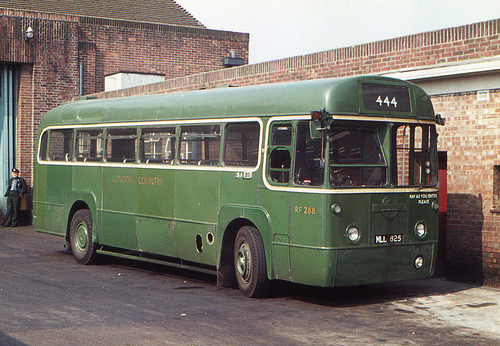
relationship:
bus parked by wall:
[37, 75, 437, 290] [74, 21, 497, 290]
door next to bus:
[407, 149, 444, 279] [37, 75, 437, 290]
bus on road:
[37, 75, 437, 290] [1, 220, 497, 342]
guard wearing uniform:
[4, 168, 28, 227] [5, 178, 27, 222]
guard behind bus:
[4, 168, 28, 227] [37, 75, 437, 290]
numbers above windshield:
[373, 91, 403, 111] [322, 118, 440, 191]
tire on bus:
[197, 230, 295, 301] [77, 66, 467, 243]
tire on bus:
[71, 208, 88, 259] [37, 75, 437, 290]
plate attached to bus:
[370, 231, 406, 241] [23, 56, 465, 325]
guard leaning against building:
[4, 168, 28, 227] [0, 55, 260, 231]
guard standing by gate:
[4, 165, 34, 231] [437, 184, 495, 307]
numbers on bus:
[376, 95, 398, 108] [8, 66, 478, 336]